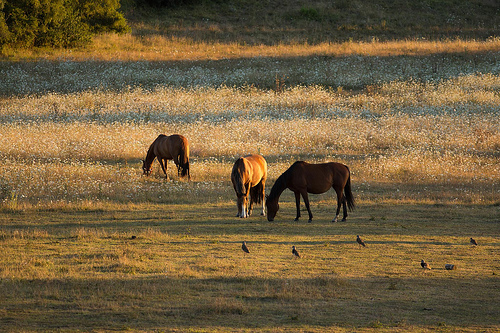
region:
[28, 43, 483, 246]
Three horses grazing in a field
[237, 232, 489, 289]
Six birds in a field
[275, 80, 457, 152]
Tall brown grass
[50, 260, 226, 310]
A green grassy area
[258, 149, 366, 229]
A brown horse that is grazing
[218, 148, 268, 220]
A brown horse with sun shining on its back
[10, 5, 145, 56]
Green bushes in the background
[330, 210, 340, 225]
A horse's white hoof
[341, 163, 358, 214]
A horse's black tail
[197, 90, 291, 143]
A sunny area in a field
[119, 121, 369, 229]
three horses in the prairie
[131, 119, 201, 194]
brown horse is eating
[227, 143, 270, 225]
horse is light brown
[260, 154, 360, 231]
horse is dark brown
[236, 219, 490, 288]
birds in the grass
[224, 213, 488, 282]
five bird near horses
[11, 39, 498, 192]
field is cover with white flowers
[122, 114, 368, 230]
three horses eating grass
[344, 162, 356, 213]
long tail of horse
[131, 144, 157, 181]
head of horse is low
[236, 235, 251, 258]
here is a little bird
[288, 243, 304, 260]
here is a little bird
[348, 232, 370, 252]
here is a little bird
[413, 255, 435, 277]
here is a little bird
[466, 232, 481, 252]
here is a little bird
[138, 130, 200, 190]
this is a horse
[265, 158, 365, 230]
this is a big horse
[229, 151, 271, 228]
this horse is eating grass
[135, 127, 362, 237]
three horses grazing in a field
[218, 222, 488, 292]
several birds standing in the grass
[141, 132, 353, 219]
three horses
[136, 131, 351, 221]
the horses are grazing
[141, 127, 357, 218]
the horses are brown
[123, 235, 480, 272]
many birds on the grass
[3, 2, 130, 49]
the bush is in the distance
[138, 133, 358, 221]
the horses are facing down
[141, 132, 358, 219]
the horses are looking down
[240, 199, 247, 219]
the horse has a white face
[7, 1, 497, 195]
the grass is long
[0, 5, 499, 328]
the scene takes place outdoors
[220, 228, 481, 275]
group of birds watching the horses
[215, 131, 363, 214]
pair of horses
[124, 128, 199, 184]
lonely horse eating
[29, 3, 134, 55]
very green bushes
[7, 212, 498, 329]
low grass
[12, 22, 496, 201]
field of flowers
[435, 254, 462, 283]
strange item in grass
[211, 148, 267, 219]
brown horse with white face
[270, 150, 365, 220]
brown horse with black tail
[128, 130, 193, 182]
brown horse with black tail